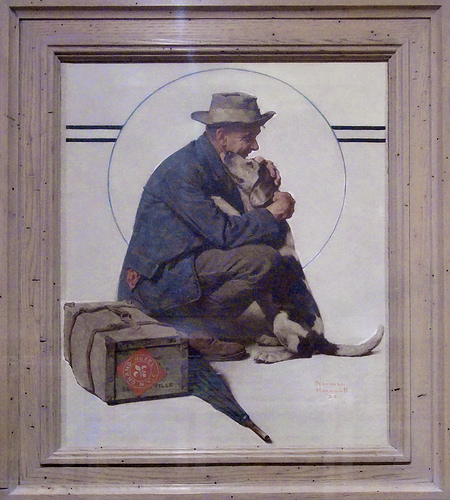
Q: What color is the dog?
A: Dark brown.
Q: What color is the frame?
A: Light grey.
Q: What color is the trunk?
A: Light brown.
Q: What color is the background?
A: White.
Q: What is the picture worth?
A: Ten dollars.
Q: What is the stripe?
A: Black.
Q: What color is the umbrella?
A: Blue.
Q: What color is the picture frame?
A: Brown.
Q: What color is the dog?
A: Black and white.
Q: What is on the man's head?
A: A hat.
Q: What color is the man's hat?
A: Brown.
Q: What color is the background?
A: White.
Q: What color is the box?
A: Tan.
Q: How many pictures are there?
A: One.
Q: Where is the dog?
A: Picture.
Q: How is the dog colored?
A: Black and white.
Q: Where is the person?
A: Picture.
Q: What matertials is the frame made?
A: Wood.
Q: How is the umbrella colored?
A: Blue.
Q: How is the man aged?
A: Older.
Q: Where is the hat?
A: Man's head.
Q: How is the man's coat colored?
A: Blue.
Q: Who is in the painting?
A: A man and a dog.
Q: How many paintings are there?
A: One.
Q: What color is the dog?
A: Black and white.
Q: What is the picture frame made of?
A: Wood.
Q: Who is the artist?
A: Norman Rockwell.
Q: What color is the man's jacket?
A: Blue.